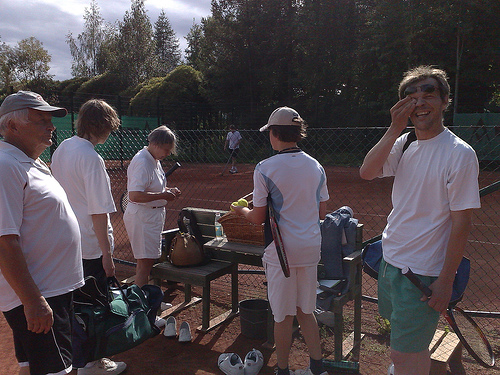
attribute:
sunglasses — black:
[404, 81, 442, 96]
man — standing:
[358, 64, 483, 375]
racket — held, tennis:
[399, 266, 496, 369]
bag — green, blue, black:
[68, 276, 155, 364]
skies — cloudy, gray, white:
[1, 1, 305, 81]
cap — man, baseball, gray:
[2, 90, 68, 119]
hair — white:
[1, 108, 31, 133]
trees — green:
[1, 1, 497, 163]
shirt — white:
[382, 127, 482, 275]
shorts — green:
[374, 254, 448, 350]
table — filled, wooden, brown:
[203, 225, 355, 270]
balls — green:
[236, 198, 249, 212]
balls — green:
[228, 201, 237, 211]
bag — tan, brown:
[166, 229, 205, 271]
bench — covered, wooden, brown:
[413, 325, 462, 375]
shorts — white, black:
[3, 287, 72, 374]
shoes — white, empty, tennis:
[216, 348, 266, 374]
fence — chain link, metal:
[1, 122, 500, 339]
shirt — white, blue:
[252, 150, 330, 266]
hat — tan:
[257, 104, 304, 133]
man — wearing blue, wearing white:
[232, 105, 333, 375]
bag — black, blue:
[360, 233, 471, 311]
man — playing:
[223, 122, 240, 174]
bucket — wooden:
[238, 296, 272, 341]